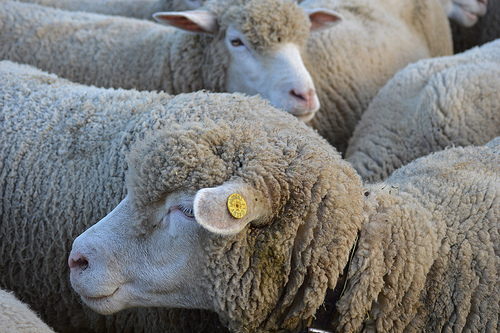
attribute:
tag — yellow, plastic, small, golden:
[228, 195, 249, 219]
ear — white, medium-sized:
[193, 180, 256, 238]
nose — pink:
[69, 250, 90, 272]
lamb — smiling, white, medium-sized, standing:
[69, 91, 498, 330]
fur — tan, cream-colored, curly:
[128, 119, 496, 332]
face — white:
[68, 174, 219, 313]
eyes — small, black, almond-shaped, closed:
[175, 205, 195, 218]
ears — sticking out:
[155, 7, 345, 32]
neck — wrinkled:
[306, 141, 375, 331]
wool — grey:
[0, 62, 204, 326]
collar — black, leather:
[317, 227, 364, 323]